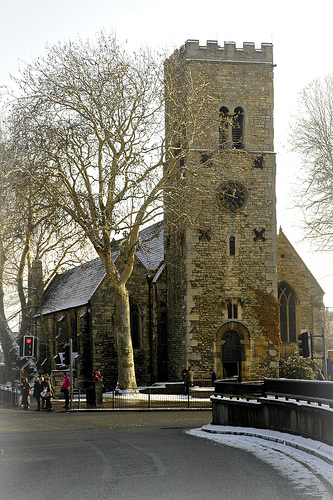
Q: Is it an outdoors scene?
A: Yes, it is outdoors.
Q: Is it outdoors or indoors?
A: It is outdoors.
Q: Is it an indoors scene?
A: No, it is outdoors.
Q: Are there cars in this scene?
A: No, there are no cars.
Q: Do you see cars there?
A: No, there are no cars.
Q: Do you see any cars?
A: No, there are no cars.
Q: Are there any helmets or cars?
A: No, there are no cars or helmets.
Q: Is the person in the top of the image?
A: No, the person is in the bottom of the image.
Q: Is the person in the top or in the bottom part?
A: The person is in the bottom of the image.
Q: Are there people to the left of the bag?
A: Yes, there is a person to the left of the bag.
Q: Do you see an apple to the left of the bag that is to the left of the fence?
A: No, there is a person to the left of the bag.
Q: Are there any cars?
A: No, there are no cars.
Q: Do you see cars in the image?
A: No, there are no cars.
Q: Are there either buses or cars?
A: No, there are no cars or buses.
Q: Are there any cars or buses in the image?
A: No, there are no cars or buses.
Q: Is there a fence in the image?
A: Yes, there is a fence.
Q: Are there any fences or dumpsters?
A: Yes, there is a fence.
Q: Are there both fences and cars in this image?
A: No, there is a fence but no cars.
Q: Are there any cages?
A: No, there are no cages.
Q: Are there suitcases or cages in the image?
A: No, there are no cages or suitcases.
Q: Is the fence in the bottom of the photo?
A: Yes, the fence is in the bottom of the image.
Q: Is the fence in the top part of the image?
A: No, the fence is in the bottom of the image.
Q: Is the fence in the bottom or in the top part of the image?
A: The fence is in the bottom of the image.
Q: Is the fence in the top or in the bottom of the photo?
A: The fence is in the bottom of the image.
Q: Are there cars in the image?
A: No, there are no cars.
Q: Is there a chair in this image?
A: No, there are no chairs.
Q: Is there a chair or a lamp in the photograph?
A: No, there are no chairs or lamps.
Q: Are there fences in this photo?
A: Yes, there is a fence.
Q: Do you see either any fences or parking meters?
A: Yes, there is a fence.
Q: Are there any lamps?
A: No, there are no lamps.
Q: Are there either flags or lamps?
A: No, there are no lamps or flags.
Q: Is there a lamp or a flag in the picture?
A: No, there are no lamps or flags.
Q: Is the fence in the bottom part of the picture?
A: Yes, the fence is in the bottom of the image.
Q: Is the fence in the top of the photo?
A: No, the fence is in the bottom of the image.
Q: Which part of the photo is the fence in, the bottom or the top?
A: The fence is in the bottom of the image.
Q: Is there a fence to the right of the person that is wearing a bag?
A: Yes, there is a fence to the right of the person.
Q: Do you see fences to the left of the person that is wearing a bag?
A: No, the fence is to the right of the person.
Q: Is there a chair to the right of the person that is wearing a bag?
A: No, there is a fence to the right of the person.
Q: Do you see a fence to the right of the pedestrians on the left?
A: Yes, there is a fence to the right of the pedestrians.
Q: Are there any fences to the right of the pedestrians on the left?
A: Yes, there is a fence to the right of the pedestrians.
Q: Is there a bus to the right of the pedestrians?
A: No, there is a fence to the right of the pedestrians.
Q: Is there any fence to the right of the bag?
A: Yes, there is a fence to the right of the bag.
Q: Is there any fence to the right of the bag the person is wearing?
A: Yes, there is a fence to the right of the bag.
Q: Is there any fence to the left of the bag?
A: No, the fence is to the right of the bag.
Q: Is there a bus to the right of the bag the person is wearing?
A: No, there is a fence to the right of the bag.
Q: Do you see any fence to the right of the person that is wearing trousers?
A: Yes, there is a fence to the right of the person.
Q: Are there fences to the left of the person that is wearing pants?
A: No, the fence is to the right of the person.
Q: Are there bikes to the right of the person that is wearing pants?
A: No, there is a fence to the right of the person.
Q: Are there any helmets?
A: No, there are no helmets.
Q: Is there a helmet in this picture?
A: No, there are no helmets.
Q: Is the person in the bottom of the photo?
A: Yes, the person is in the bottom of the image.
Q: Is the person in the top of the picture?
A: No, the person is in the bottom of the image.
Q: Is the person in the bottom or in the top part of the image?
A: The person is in the bottom of the image.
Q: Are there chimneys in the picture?
A: No, there are no chimneys.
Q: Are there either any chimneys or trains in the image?
A: No, there are no chimneys or trains.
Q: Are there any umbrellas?
A: No, there are no umbrellas.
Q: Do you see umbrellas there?
A: No, there are no umbrellas.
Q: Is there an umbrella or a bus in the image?
A: No, there are no umbrellas or buses.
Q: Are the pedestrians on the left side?
A: Yes, the pedestrians are on the left of the image.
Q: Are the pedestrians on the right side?
A: No, the pedestrians are on the left of the image.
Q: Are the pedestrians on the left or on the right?
A: The pedestrians are on the left of the image.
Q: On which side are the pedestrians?
A: The pedestrians are on the left of the image.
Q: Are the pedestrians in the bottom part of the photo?
A: Yes, the pedestrians are in the bottom of the image.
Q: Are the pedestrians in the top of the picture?
A: No, the pedestrians are in the bottom of the image.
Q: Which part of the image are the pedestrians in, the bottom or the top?
A: The pedestrians are in the bottom of the image.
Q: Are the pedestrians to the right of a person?
A: No, the pedestrians are to the left of a person.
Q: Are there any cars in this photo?
A: No, there are no cars.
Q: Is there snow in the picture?
A: Yes, there is snow.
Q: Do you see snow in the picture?
A: Yes, there is snow.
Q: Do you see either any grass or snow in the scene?
A: Yes, there is snow.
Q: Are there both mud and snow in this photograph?
A: No, there is snow but no mud.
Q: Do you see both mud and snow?
A: No, there is snow but no mud.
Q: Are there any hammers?
A: No, there are no hammers.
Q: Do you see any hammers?
A: No, there are no hammers.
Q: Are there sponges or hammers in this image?
A: No, there are no hammers or sponges.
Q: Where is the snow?
A: The snow is on the ground.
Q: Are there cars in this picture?
A: No, there are no cars.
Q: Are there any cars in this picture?
A: No, there are no cars.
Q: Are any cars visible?
A: No, there are no cars.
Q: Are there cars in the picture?
A: No, there are no cars.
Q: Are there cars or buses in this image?
A: No, there are no cars or buses.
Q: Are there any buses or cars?
A: No, there are no cars or buses.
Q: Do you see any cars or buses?
A: No, there are no cars or buses.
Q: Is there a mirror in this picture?
A: No, there are no mirrors.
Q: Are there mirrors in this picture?
A: No, there are no mirrors.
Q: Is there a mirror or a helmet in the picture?
A: No, there are no mirrors or helmets.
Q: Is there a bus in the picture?
A: No, there are no buses.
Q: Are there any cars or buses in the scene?
A: No, there are no buses or cars.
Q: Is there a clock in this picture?
A: Yes, there is a clock.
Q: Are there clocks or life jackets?
A: Yes, there is a clock.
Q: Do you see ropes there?
A: No, there are no ropes.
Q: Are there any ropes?
A: No, there are no ropes.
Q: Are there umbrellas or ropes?
A: No, there are no ropes or umbrellas.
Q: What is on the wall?
A: The clock is on the wall.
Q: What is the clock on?
A: The clock is on the wall.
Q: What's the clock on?
A: The clock is on the wall.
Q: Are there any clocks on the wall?
A: Yes, there is a clock on the wall.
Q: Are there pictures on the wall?
A: No, there is a clock on the wall.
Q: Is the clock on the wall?
A: Yes, the clock is on the wall.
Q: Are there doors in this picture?
A: Yes, there is a door.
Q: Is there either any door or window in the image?
A: Yes, there is a door.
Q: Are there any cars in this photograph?
A: No, there are no cars.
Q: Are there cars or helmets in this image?
A: No, there are no cars or helmets.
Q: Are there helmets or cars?
A: No, there are no cars or helmets.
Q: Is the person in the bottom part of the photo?
A: Yes, the person is in the bottom of the image.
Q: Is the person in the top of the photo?
A: No, the person is in the bottom of the image.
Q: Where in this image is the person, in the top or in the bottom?
A: The person is in the bottom of the image.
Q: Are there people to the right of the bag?
A: Yes, there is a person to the right of the bag.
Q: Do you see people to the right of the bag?
A: Yes, there is a person to the right of the bag.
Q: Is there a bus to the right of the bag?
A: No, there is a person to the right of the bag.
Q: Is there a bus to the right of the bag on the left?
A: No, there is a person to the right of the bag.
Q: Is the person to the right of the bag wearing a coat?
A: Yes, the person is wearing a coat.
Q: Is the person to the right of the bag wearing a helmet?
A: No, the person is wearing a coat.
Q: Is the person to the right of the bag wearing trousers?
A: Yes, the person is wearing trousers.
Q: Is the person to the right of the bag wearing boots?
A: No, the person is wearing trousers.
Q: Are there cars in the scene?
A: No, there are no cars.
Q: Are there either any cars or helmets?
A: No, there are no cars or helmets.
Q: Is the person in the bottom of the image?
A: Yes, the person is in the bottom of the image.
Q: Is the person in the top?
A: No, the person is in the bottom of the image.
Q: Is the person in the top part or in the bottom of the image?
A: The person is in the bottom of the image.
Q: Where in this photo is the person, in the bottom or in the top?
A: The person is in the bottom of the image.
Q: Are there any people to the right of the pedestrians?
A: Yes, there is a person to the right of the pedestrians.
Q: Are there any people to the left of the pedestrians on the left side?
A: No, the person is to the right of the pedestrians.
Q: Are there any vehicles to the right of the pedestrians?
A: No, there is a person to the right of the pedestrians.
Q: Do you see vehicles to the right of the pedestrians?
A: No, there is a person to the right of the pedestrians.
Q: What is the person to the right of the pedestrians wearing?
A: The person is wearing a coat.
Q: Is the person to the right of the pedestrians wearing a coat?
A: Yes, the person is wearing a coat.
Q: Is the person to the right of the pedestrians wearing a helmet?
A: No, the person is wearing a coat.